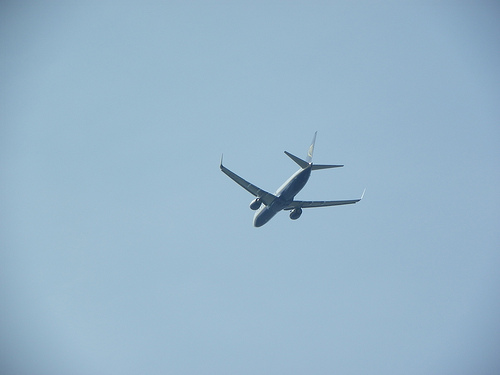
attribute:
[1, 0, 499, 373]
sky — blue, clear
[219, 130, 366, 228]
airplane — white, big, aircraft, metallic, blue, small, metal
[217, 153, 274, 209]
left wing — to the left, sharp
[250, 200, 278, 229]
front — streamlined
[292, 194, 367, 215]
wing — sharp, long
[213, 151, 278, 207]
wing — long